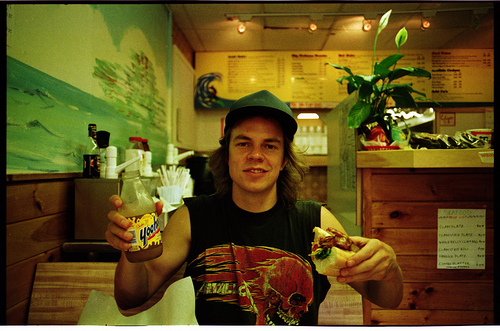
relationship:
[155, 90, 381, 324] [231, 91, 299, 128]
man wearing hat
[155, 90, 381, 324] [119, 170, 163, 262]
man holding bottle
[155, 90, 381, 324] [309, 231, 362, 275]
man holding sandwich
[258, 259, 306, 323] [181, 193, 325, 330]
red skull on shirt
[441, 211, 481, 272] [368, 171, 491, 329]
paper on wall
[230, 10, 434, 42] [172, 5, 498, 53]
lights on ceiling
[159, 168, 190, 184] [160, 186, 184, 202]
straws in cup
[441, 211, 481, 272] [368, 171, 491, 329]
menu taped to wall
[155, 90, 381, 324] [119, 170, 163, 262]
man holding chocolate milk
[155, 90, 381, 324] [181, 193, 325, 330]
man wearing tank top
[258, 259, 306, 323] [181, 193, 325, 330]
red skull on tank top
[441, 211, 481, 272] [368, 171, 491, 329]
paper hanging on wall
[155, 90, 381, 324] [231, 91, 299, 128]
man wearing a hat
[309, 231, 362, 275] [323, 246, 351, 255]
sandwich with sauce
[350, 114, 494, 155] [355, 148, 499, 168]
items on counter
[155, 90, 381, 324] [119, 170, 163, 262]
man holding drink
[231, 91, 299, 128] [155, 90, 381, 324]
hat on man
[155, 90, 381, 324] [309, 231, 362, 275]
man holding food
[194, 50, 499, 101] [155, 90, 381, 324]
menu behind man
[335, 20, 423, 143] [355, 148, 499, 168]
plant on counter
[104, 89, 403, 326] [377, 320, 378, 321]
man sitting at table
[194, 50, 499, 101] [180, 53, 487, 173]
menu on wall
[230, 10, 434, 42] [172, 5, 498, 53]
lights lined up on ceiling